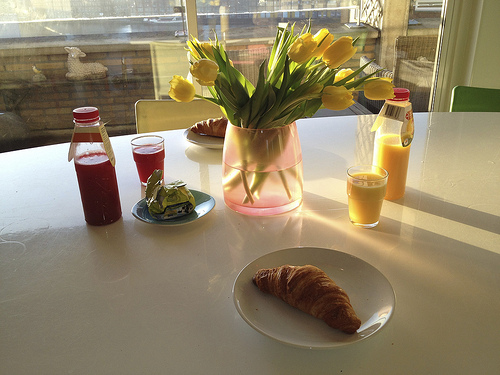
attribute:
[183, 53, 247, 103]
roses — yellow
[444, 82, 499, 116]
chair — green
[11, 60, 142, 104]
wall — brick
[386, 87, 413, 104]
cap — red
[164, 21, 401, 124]
flowers — yellow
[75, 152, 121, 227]
juice — red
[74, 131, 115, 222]
juice — red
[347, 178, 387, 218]
juice — orange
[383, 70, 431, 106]
cap — red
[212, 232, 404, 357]
dish — white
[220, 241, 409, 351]
plate — white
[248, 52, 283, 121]
stem — green